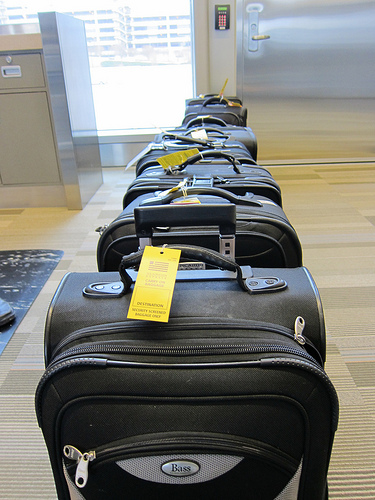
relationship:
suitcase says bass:
[48, 254, 339, 499] [158, 455, 208, 477]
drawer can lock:
[2, 34, 65, 208] [5, 50, 16, 65]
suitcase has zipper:
[48, 254, 339, 499] [52, 324, 323, 371]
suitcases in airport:
[30, 232, 349, 495] [0, 1, 359, 497]